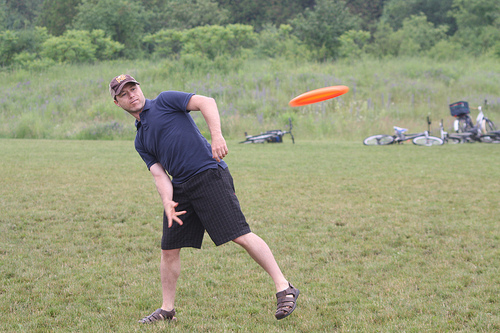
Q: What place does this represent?
A: It represents the field.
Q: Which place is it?
A: It is a field.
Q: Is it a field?
A: Yes, it is a field.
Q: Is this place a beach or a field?
A: It is a field.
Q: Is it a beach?
A: No, it is a field.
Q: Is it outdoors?
A: Yes, it is outdoors.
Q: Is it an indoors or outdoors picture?
A: It is outdoors.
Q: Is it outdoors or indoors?
A: It is outdoors.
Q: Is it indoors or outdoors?
A: It is outdoors.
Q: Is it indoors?
A: No, it is outdoors.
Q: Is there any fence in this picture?
A: No, there are no fences.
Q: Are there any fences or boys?
A: No, there are no fences or boys.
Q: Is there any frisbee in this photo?
A: Yes, there is a frisbee.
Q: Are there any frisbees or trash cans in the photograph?
A: Yes, there is a frisbee.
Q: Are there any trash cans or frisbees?
A: Yes, there is a frisbee.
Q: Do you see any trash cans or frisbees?
A: Yes, there is a frisbee.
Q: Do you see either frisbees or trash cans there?
A: Yes, there is a frisbee.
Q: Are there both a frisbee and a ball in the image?
A: No, there is a frisbee but no balls.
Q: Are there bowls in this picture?
A: No, there are no bowls.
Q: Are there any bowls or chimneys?
A: No, there are no bowls or chimneys.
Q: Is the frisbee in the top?
A: Yes, the frisbee is in the top of the image.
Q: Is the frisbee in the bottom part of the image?
A: No, the frisbee is in the top of the image.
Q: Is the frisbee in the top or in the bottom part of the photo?
A: The frisbee is in the top of the image.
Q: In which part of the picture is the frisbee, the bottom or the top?
A: The frisbee is in the top of the image.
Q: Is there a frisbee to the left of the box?
A: Yes, there is a frisbee to the left of the box.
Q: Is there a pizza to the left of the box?
A: No, there is a frisbee to the left of the box.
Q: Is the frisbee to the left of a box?
A: Yes, the frisbee is to the left of a box.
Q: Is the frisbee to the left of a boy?
A: No, the frisbee is to the left of a box.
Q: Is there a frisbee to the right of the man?
A: Yes, there is a frisbee to the right of the man.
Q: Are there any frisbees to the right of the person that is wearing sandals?
A: Yes, there is a frisbee to the right of the man.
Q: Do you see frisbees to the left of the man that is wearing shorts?
A: No, the frisbee is to the right of the man.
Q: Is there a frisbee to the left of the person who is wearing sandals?
A: No, the frisbee is to the right of the man.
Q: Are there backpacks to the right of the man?
A: No, there is a frisbee to the right of the man.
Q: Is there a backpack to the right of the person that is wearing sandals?
A: No, there is a frisbee to the right of the man.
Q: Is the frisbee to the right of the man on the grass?
A: Yes, the frisbee is to the right of the man.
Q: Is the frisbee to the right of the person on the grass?
A: Yes, the frisbee is to the right of the man.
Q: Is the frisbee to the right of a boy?
A: No, the frisbee is to the right of the man.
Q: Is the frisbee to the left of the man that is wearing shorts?
A: No, the frisbee is to the right of the man.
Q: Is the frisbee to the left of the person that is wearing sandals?
A: No, the frisbee is to the right of the man.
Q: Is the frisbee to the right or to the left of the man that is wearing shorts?
A: The frisbee is to the right of the man.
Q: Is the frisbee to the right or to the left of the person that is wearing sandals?
A: The frisbee is to the right of the man.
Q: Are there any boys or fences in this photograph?
A: No, there are no boys or fences.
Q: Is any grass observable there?
A: Yes, there is grass.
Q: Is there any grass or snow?
A: Yes, there is grass.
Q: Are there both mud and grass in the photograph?
A: No, there is grass but no mud.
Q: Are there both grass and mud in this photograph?
A: No, there is grass but no mud.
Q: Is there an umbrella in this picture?
A: No, there are no umbrellas.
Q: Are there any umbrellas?
A: No, there are no umbrellas.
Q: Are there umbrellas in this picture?
A: No, there are no umbrellas.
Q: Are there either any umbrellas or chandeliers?
A: No, there are no umbrellas or chandeliers.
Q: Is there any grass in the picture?
A: Yes, there is grass.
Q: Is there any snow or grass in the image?
A: Yes, there is grass.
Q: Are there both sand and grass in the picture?
A: No, there is grass but no sand.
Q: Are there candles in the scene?
A: No, there are no candles.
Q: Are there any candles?
A: No, there are no candles.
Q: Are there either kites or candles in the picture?
A: No, there are no candles or kites.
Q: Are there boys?
A: No, there are no boys.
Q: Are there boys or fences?
A: No, there are no boys or fences.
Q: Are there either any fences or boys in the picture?
A: No, there are no boys or fences.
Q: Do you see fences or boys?
A: No, there are no boys or fences.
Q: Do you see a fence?
A: No, there are no fences.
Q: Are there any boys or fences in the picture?
A: No, there are no fences or boys.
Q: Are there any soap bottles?
A: No, there are no soap bottles.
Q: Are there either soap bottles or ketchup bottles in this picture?
A: No, there are no soap bottles or ketchup bottles.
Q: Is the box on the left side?
A: No, the box is on the right of the image.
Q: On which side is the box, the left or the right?
A: The box is on the right of the image.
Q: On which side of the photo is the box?
A: The box is on the right of the image.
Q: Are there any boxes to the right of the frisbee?
A: Yes, there is a box to the right of the frisbee.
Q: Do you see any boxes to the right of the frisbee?
A: Yes, there is a box to the right of the frisbee.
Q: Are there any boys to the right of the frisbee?
A: No, there is a box to the right of the frisbee.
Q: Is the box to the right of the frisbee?
A: Yes, the box is to the right of the frisbee.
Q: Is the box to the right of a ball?
A: No, the box is to the right of the frisbee.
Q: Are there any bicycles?
A: Yes, there is a bicycle.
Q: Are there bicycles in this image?
A: Yes, there is a bicycle.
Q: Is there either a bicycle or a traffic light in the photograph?
A: Yes, there is a bicycle.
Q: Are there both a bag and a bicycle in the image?
A: No, there is a bicycle but no bags.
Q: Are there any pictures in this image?
A: No, there are no pictures.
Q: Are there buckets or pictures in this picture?
A: No, there are no pictures or buckets.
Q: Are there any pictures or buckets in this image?
A: No, there are no pictures or buckets.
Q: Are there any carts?
A: No, there are no carts.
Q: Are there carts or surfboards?
A: No, there are no carts or surfboards.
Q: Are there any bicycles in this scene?
A: Yes, there is a bicycle.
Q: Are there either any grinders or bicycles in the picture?
A: Yes, there is a bicycle.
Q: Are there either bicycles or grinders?
A: Yes, there is a bicycle.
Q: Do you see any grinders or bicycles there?
A: Yes, there is a bicycle.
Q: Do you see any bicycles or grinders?
A: Yes, there is a bicycle.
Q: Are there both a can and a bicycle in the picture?
A: No, there is a bicycle but no cans.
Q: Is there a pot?
A: No, there are no pots.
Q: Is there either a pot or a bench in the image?
A: No, there are no pots or benches.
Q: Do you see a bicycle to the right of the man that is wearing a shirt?
A: Yes, there is a bicycle to the right of the man.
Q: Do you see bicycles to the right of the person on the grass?
A: Yes, there is a bicycle to the right of the man.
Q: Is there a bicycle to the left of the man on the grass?
A: No, the bicycle is to the right of the man.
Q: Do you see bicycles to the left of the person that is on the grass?
A: No, the bicycle is to the right of the man.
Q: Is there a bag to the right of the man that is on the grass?
A: No, there is a bicycle to the right of the man.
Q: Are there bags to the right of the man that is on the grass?
A: No, there is a bicycle to the right of the man.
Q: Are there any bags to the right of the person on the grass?
A: No, there is a bicycle to the right of the man.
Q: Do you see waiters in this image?
A: No, there are no waiters.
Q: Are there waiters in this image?
A: No, there are no waiters.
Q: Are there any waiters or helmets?
A: No, there are no waiters or helmets.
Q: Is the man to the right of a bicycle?
A: No, the man is to the left of a bicycle.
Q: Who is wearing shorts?
A: The man is wearing shorts.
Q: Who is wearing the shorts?
A: The man is wearing shorts.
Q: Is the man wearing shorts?
A: Yes, the man is wearing shorts.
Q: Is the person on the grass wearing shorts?
A: Yes, the man is wearing shorts.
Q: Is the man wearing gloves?
A: No, the man is wearing shorts.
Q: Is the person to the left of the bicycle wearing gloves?
A: No, the man is wearing shorts.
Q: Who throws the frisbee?
A: The man throws the frisbee.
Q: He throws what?
A: The man throws the frisbee.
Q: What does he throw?
A: The man throws the frisbee.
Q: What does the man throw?
A: The man throws the frisbee.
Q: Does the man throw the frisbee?
A: Yes, the man throws the frisbee.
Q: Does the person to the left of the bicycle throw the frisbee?
A: Yes, the man throws the frisbee.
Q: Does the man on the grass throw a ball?
A: No, the man throws the frisbee.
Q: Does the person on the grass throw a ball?
A: No, the man throws the frisbee.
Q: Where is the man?
A: The man is on the grass.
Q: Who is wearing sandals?
A: The man is wearing sandals.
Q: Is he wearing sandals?
A: Yes, the man is wearing sandals.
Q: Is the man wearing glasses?
A: No, the man is wearing sandals.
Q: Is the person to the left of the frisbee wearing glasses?
A: No, the man is wearing sandals.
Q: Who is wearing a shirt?
A: The man is wearing a shirt.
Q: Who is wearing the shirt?
A: The man is wearing a shirt.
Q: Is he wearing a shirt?
A: Yes, the man is wearing a shirt.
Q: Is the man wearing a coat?
A: No, the man is wearing a shirt.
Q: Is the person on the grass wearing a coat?
A: No, the man is wearing a shirt.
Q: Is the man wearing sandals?
A: Yes, the man is wearing sandals.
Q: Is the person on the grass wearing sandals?
A: Yes, the man is wearing sandals.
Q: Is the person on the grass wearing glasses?
A: No, the man is wearing sandals.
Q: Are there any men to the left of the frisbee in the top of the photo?
A: Yes, there is a man to the left of the frisbee.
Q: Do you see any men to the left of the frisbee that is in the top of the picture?
A: Yes, there is a man to the left of the frisbee.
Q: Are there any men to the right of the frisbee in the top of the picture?
A: No, the man is to the left of the frisbee.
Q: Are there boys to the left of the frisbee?
A: No, there is a man to the left of the frisbee.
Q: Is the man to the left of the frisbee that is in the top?
A: Yes, the man is to the left of the frisbee.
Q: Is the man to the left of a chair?
A: No, the man is to the left of the frisbee.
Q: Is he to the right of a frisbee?
A: No, the man is to the left of a frisbee.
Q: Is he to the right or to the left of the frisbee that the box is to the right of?
A: The man is to the left of the frisbee.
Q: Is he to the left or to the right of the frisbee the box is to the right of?
A: The man is to the left of the frisbee.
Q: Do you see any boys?
A: No, there are no boys.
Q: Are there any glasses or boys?
A: No, there are no boys or glasses.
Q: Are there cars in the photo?
A: No, there are no cars.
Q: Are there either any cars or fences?
A: No, there are no cars or fences.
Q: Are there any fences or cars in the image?
A: No, there are no cars or fences.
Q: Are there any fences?
A: No, there are no fences.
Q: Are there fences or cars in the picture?
A: No, there are no fences or cars.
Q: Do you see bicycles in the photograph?
A: Yes, there are bicycles.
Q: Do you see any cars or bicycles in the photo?
A: Yes, there are bicycles.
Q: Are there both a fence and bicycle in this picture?
A: No, there are bicycles but no fences.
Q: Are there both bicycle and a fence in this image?
A: No, there are bicycles but no fences.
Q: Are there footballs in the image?
A: No, there are no footballs.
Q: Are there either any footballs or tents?
A: No, there are no footballs or tents.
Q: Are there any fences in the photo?
A: No, there are no fences.